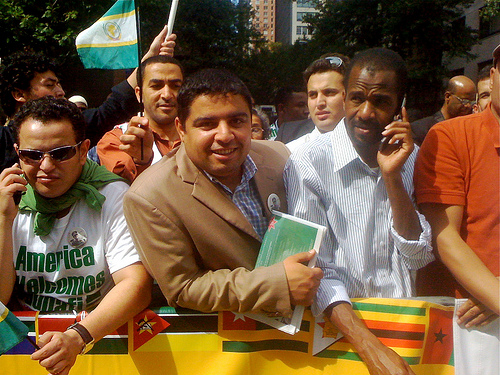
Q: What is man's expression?
A: Smiling.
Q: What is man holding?
A: Paper.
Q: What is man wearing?
A: Jacket.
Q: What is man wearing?
A: Scarf.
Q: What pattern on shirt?
A: Stripes.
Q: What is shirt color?
A: Orange.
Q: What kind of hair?
A: Short.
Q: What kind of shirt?
A: Jacket.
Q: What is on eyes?
A: Sunglasses.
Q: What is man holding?
A: Cell phone.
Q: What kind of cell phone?
A: Flip phone.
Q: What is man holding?
A: Paper.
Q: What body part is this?
A: Head.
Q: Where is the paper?
A: Man's hand.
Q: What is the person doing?
A: Holding newspaper.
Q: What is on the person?
A: White and blue shirt.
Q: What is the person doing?
A: Holding cell phone.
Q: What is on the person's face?
A: Smile.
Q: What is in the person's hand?
A: Green and white flag.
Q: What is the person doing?
A: Holding flag.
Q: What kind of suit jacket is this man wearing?
A: A brown suit jacket.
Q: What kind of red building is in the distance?
A: A brick building.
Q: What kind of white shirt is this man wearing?
A: A striped shirt.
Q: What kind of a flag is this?
A: A green and white flag.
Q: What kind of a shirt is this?
A: A dark orange shirt.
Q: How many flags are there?
A: Two.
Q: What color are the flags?
A: Green, white, and yellow.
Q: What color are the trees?
A: Green.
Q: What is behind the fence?
A: A crowd of people.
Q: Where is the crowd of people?
A: Behind the fence.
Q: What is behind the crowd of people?
A: Trees.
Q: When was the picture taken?
A: Daytime.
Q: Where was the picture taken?
A: At an outdoor function.